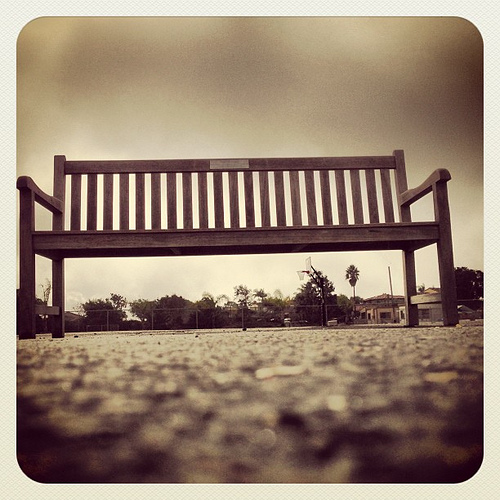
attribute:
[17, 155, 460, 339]
bench — brown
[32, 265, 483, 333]
trees — tall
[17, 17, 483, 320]
sky — dark, gray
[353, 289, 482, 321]
structures — brown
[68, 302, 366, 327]
fence — long